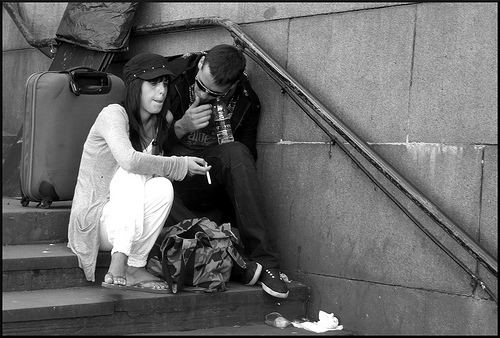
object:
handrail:
[1, 4, 498, 280]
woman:
[67, 56, 212, 295]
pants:
[99, 166, 173, 267]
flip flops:
[124, 273, 172, 295]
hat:
[122, 53, 178, 83]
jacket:
[65, 104, 187, 281]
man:
[161, 42, 292, 298]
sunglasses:
[195, 67, 230, 99]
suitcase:
[18, 68, 126, 208]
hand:
[174, 94, 214, 141]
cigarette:
[204, 164, 211, 183]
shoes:
[256, 267, 291, 297]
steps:
[2, 284, 351, 336]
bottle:
[215, 98, 234, 144]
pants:
[165, 142, 283, 271]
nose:
[201, 89, 208, 103]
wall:
[2, 4, 498, 336]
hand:
[187, 155, 212, 178]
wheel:
[19, 199, 31, 206]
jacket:
[164, 54, 259, 161]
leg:
[195, 143, 279, 268]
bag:
[152, 216, 246, 292]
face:
[195, 63, 232, 105]